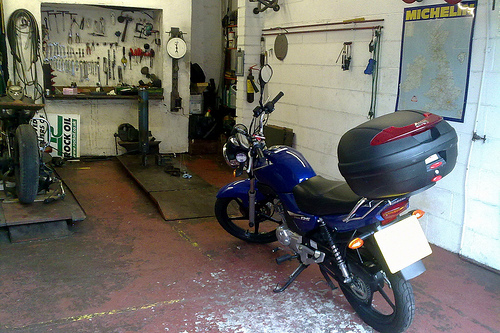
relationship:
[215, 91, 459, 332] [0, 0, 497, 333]
motorcycle inside of garage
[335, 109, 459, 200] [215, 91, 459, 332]
cargo container on top of motorcycle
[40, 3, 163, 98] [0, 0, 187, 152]
tools hanging on wall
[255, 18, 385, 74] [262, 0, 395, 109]
tools hanging on wall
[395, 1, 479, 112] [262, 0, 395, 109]
sign hanging on wall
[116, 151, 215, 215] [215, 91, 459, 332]
lift for motorcycle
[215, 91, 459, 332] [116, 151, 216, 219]
motorcycle on top of motorcycle lift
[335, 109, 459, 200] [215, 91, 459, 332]
storage container on back of motorcycle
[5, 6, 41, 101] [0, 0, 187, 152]
wires hanging on wall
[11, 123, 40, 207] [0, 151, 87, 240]
tire on top of rack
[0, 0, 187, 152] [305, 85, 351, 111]
wall made of cement brick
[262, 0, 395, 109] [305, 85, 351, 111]
wall made of cement brick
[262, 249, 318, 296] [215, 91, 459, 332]
kickstand on motorcycle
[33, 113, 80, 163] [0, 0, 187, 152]
sign leaning against wall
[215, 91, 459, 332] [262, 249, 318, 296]
motorcycle has kickstand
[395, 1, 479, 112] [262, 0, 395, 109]
map hanging on wall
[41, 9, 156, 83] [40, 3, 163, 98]
array of tools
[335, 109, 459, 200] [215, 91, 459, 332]
storage compartment on top of bike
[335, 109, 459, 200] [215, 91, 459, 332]
cargo container attached to motorcycle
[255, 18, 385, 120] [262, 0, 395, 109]
tools hanging on wall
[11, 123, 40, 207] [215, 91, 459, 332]
tire for motorcycle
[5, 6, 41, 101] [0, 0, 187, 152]
hose hanging on wall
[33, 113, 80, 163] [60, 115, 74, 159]
sign says rock oil